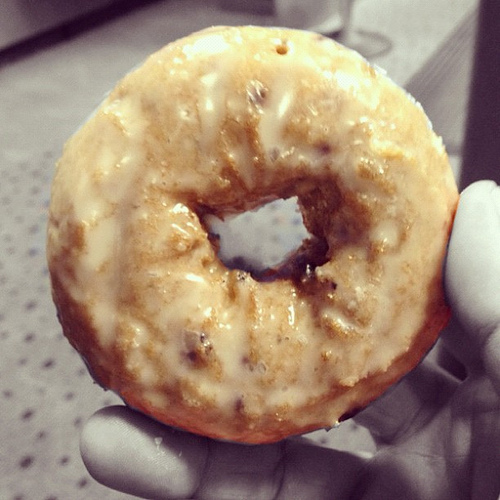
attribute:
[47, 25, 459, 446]
donut — glazed, brown, round, iced, big, large, bubbling, sugar coated, white, whole, cream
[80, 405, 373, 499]
finger — ring finger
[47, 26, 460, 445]
glaze — white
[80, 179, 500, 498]
hand — big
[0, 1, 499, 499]
background — black, white